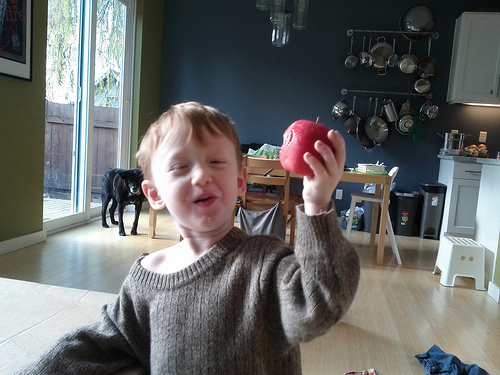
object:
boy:
[17, 102, 363, 372]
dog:
[100, 168, 144, 237]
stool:
[431, 236, 488, 291]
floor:
[344, 225, 500, 340]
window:
[91, 16, 124, 210]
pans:
[343, 36, 359, 69]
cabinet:
[436, 156, 497, 239]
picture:
[0, 0, 30, 81]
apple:
[278, 112, 337, 178]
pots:
[399, 53, 415, 73]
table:
[236, 157, 390, 265]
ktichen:
[0, 0, 499, 375]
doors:
[44, 18, 92, 222]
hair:
[134, 101, 242, 179]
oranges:
[466, 144, 477, 152]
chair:
[347, 167, 405, 267]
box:
[390, 190, 422, 234]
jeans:
[403, 345, 493, 374]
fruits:
[246, 138, 280, 161]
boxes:
[416, 182, 447, 239]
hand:
[301, 130, 346, 212]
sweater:
[29, 207, 363, 374]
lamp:
[249, 25, 309, 73]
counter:
[437, 155, 483, 233]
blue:
[206, 32, 292, 134]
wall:
[0, 16, 45, 254]